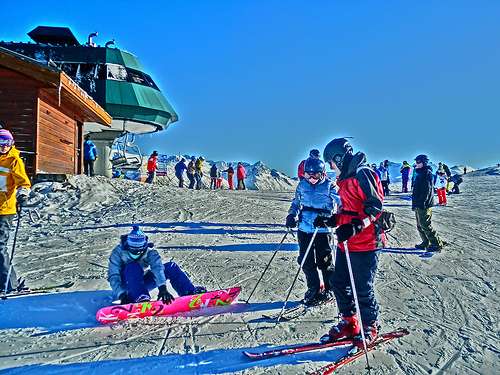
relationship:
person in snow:
[111, 227, 204, 298] [4, 158, 498, 365]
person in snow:
[408, 153, 445, 250] [4, 158, 498, 365]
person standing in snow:
[233, 159, 249, 189] [186, 191, 280, 204]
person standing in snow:
[312, 134, 386, 344] [400, 254, 498, 349]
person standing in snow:
[410, 153, 445, 253] [400, 254, 498, 349]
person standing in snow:
[286, 155, 338, 304] [400, 254, 498, 349]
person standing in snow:
[0, 129, 33, 304] [400, 254, 498, 349]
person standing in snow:
[144, 147, 158, 181] [400, 254, 498, 349]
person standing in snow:
[0, 129, 33, 304] [24, 168, 491, 373]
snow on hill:
[286, 260, 495, 374] [119, 140, 306, 203]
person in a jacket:
[286, 155, 338, 304] [287, 179, 338, 234]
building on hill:
[21, 64, 163, 188] [1, 173, 211, 222]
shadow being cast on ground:
[144, 210, 279, 262] [213, 192, 266, 237]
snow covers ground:
[172, 203, 258, 253] [1, 173, 485, 373]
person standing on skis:
[312, 134, 386, 344] [244, 327, 408, 374]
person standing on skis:
[286, 155, 338, 304] [267, 288, 332, 322]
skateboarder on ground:
[94, 224, 215, 302] [18, 169, 498, 366]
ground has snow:
[18, 169, 498, 366] [0, 135, 495, 374]